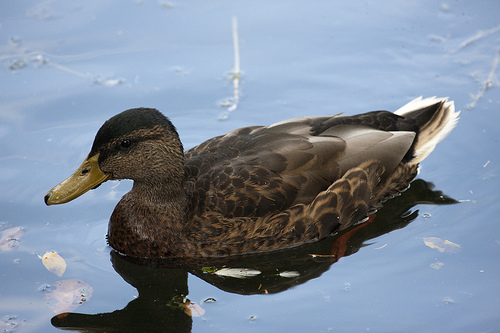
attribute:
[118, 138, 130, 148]
right eye — small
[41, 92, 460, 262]
duck — brown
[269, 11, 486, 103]
water — dark, blue, calm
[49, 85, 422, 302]
duck — brown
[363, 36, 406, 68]
water — blue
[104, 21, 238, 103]
water — blue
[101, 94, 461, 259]
feathers — brown, black, spotted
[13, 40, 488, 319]
water — blue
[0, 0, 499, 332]
blue water — clear, light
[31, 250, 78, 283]
leaves — orange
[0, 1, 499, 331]
water — blue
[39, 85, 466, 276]
duck — brown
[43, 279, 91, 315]
leaves — floating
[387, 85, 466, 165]
tail — white, feathered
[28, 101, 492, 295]
duck — brown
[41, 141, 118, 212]
beak — large, brown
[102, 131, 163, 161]
line — black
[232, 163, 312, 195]
feathers — wing feathers